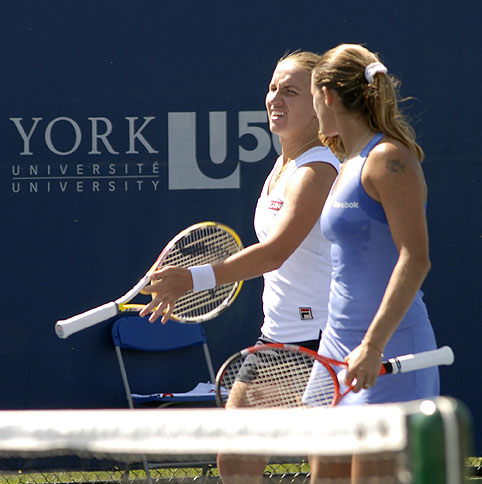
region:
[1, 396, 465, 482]
a tennis court net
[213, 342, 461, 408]
woman holding a red tennis racket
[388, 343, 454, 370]
white handle of a tennis racket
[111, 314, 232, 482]
a blue metal chair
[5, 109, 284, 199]
advertisement on a blue tarp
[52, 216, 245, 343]
woman holding a yellow tennis racket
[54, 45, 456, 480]
two women holding tennis rackets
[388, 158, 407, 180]
a tattoo on woman's shoulder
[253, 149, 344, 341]
woman wearing a white tank top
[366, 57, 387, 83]
a white scrunchie in woman's head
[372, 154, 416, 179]
tattoo on woman's arm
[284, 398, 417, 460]
top of tennis court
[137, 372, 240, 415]
towel on blue chair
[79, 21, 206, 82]
blue wall in the background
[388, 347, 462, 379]
white handle on racket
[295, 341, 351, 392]
red color on the racket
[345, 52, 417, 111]
white pony tail holder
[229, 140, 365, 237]
short sleeve white shirt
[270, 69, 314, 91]
frown on woman's forehead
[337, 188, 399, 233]
stain under woman's under arm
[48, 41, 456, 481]
two women are walking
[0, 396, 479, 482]
tennis net attached to green pole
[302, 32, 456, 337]
a woman wearing a blue shirt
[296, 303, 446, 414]
a woman wearing a blue skirt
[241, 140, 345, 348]
a woman wearing a white shirt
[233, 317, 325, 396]
a woman wearing a black skirt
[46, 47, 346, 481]
a woman holding yellow tennis racket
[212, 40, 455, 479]
a woman holding a red tennis racket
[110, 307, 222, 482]
a blue folding chair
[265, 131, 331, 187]
a woman wearing a gold necklace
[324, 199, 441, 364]
the top is blue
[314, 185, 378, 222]
the brand is reebook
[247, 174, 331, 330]
the shirt is white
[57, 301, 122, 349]
the handle is white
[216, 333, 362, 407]
the frame is red and white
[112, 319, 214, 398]
the chair is blue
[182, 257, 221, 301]
the wrist band is white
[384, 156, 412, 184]
tatoo is on her skin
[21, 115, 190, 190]
the letters are york universite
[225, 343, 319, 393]
the shorts are black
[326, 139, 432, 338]
the woman is wearing a tank top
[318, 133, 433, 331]
the shirt is blue in color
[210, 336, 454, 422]
the woman is holding a racket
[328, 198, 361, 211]
the shirt has lettering on it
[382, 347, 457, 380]
the racket has a white handle on it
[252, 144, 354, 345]
the woman is wearing a tank top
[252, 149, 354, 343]
the shirt is white in color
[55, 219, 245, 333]
the woman is holding a racket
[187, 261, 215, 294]
the woman has a wrist band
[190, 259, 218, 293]
the wrist band is white in color